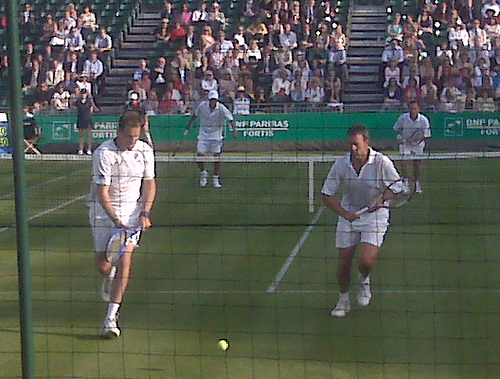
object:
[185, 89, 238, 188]
player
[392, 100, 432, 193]
player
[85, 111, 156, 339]
player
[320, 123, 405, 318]
player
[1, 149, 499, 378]
court